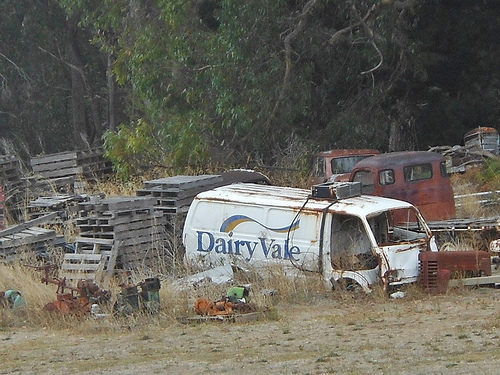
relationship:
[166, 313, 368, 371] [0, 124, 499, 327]
grass in dumpsite